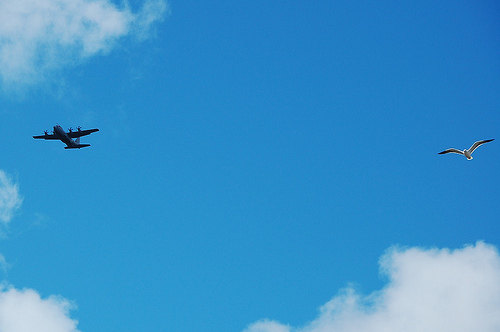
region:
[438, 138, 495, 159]
seagull in flight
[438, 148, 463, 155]
gliding wing of seagull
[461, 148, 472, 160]
white body of a seagull in flight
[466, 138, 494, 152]
extended wing of a seagull in flight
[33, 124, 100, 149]
airplane in the sky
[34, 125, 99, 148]
grey prop plane in flight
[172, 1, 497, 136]
cloudless portion of blue sky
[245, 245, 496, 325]
gray and white cloud with blue sky behind it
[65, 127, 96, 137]
wing of airplane with two prop engines on it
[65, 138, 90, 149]
grey tail section of an airplane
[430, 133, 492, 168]
bird soaring in the sky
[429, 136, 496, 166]
bird flying in the sky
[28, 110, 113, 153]
airplane flying in the sky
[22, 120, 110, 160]
airplane soaring in the sky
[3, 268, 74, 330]
white fluffy cloud in the sky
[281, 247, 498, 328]
white fluffy cloud in the sky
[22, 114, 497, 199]
bird and airplane flying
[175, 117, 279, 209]
clear part of blue sky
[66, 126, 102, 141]
left airplane wing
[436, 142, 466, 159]
right white wing of bird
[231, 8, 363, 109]
this is the sky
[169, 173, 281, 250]
the sky is blue in color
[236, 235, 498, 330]
the sky has some clouds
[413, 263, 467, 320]
the clouds are white in color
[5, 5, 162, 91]
the cloud is big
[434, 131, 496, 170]
this is a bird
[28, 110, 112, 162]
this is an airplane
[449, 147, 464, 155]
the feathers are white in color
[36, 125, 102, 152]
the airplane is in the air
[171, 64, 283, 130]
the sky is clear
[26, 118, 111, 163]
A plane in the sky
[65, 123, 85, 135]
Two propellers on the wing of the plane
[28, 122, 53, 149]
The other wing with one visible propeller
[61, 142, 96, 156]
The wings of the planes tail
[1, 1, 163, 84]
The fading clouds in the sky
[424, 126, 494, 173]
The bird flying in the air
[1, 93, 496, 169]
The bird and plane flying through the air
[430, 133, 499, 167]
The black tops on the birds wings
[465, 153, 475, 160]
The tail feathers if the bird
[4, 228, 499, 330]
The clouds under the flying objects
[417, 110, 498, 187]
this is a bird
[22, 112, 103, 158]
this is a plane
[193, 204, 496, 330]
this is a cloud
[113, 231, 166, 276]
this is the sky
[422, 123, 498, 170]
this bird is flying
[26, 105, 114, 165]
this bird is flying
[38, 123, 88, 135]
these are some propellers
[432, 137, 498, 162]
these are the wings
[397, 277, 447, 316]
this is the color white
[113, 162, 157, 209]
this is the color blue